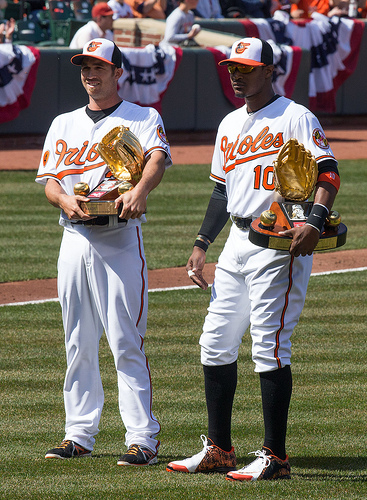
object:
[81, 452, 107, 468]
green grass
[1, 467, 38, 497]
grasses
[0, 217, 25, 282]
grasses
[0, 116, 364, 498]
field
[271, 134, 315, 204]
award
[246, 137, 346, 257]
trophy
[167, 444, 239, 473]
shoe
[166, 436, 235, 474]
foot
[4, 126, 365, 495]
baseball field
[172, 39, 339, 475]
guy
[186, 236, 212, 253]
band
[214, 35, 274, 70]
hat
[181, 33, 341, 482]
man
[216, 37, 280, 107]
head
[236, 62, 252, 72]
lens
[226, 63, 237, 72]
lens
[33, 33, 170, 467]
baseball players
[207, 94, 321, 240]
t-shirt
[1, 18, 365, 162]
fence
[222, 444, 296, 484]
shoe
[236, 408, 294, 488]
left foot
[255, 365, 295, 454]
sock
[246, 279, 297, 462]
leg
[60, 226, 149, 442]
pants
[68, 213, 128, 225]
belt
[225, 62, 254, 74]
sunglasses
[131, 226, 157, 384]
pants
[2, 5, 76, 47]
people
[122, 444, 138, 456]
laces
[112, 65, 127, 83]
left ear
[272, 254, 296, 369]
stripe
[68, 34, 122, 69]
hat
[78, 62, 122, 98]
head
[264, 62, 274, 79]
ear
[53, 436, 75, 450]
laces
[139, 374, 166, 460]
stripe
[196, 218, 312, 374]
pants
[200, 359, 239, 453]
sock